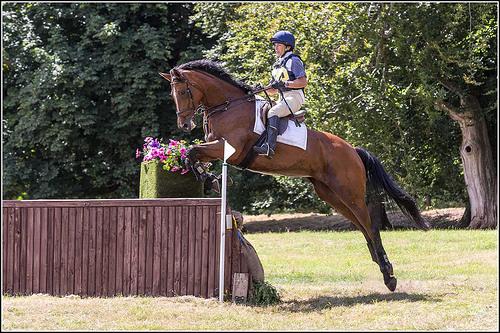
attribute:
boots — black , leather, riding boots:
[251, 117, 283, 171]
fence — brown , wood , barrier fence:
[3, 194, 254, 311]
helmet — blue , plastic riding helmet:
[270, 27, 297, 49]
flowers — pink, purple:
[134, 131, 213, 180]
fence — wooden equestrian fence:
[3, 198, 265, 303]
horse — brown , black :
[148, 61, 468, 293]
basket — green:
[134, 155, 206, 197]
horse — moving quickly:
[158, 60, 428, 291]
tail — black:
[358, 145, 433, 234]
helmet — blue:
[268, 29, 296, 51]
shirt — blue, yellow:
[266, 56, 309, 102]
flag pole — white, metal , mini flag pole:
[217, 162, 227, 302]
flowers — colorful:
[133, 132, 213, 175]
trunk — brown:
[426, 80, 498, 244]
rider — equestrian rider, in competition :
[252, 30, 304, 155]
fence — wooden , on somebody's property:
[0, 192, 229, 299]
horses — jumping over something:
[139, 57, 431, 295]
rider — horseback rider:
[253, 14, 360, 226]